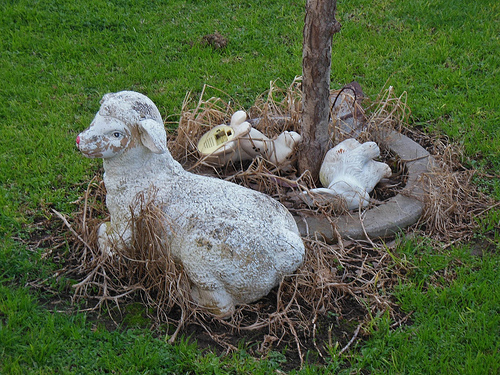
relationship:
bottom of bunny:
[190, 122, 235, 154] [198, 110, 300, 162]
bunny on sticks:
[299, 138, 393, 211] [258, 177, 390, 214]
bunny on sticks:
[299, 139, 380, 204] [278, 220, 396, 297]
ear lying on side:
[298, 184, 335, 204] [302, 123, 392, 210]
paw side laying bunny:
[359, 139, 384, 159] [299, 138, 393, 211]